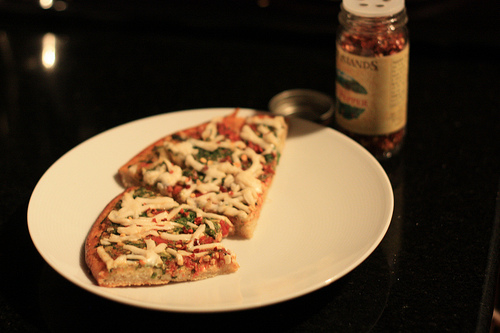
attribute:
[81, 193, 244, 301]
of pizza — smaller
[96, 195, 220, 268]
shredded cheese — on top, white, unmelted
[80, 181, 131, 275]
crust — curved, narrow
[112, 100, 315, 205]
one pizza slice — larger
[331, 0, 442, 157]
container — small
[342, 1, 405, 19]
covering — white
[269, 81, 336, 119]
lid — back of plate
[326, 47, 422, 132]
label — paper, yellow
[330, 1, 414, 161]
bottle — one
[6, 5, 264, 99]
table — black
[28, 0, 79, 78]
reflection — light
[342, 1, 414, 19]
cover — white, slotted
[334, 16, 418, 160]
spice container — small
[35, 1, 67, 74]
light — reflected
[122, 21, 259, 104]
surface — black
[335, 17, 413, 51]
plastic — small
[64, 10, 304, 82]
black surface — solid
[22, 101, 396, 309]
one plate — white, round shaped, plain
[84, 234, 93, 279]
outer edge — brown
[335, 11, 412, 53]
jar — clear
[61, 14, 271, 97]
tabletop — black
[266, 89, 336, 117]
cover — silver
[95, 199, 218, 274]
cheese — mozzarella, white, shredded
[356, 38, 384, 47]
pepper flakes — red, crushed